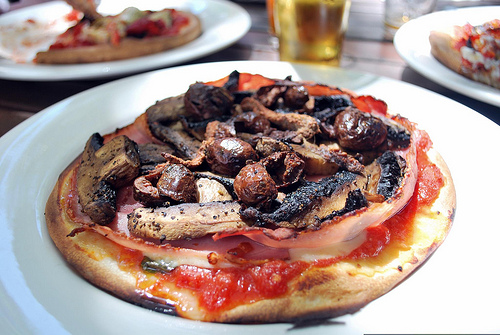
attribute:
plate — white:
[1, 58, 499, 333]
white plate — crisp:
[2, 66, 499, 331]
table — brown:
[1, 0, 498, 135]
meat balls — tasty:
[147, 58, 377, 261]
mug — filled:
[263, 0, 355, 72]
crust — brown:
[44, 151, 456, 321]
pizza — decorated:
[40, 67, 459, 324]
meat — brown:
[81, 97, 330, 261]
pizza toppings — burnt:
[70, 69, 417, 268]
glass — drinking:
[275, 0, 348, 64]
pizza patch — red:
[164, 257, 306, 307]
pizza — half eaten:
[26, 3, 204, 66]